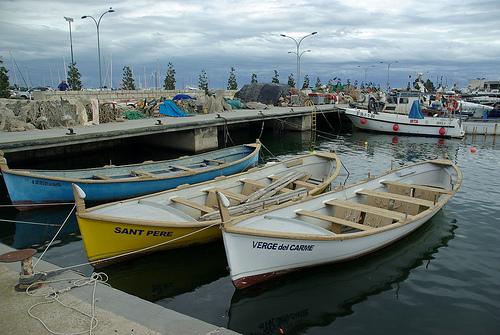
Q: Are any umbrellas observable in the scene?
A: No, there are no umbrellas.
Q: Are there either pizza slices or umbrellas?
A: No, there are no umbrellas or pizza slices.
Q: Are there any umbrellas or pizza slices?
A: No, there are no umbrellas or pizza slices.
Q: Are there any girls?
A: No, there are no girls.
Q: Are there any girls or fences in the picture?
A: No, there are no girls or fences.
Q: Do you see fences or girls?
A: No, there are no girls or fences.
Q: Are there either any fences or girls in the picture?
A: No, there are no girls or fences.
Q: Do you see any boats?
A: Yes, there is a boat.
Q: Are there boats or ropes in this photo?
A: Yes, there is a boat.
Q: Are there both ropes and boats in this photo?
A: Yes, there are both a boat and a rope.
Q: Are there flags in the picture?
A: No, there are no flags.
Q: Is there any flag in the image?
A: No, there are no flags.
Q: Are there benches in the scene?
A: Yes, there is a bench.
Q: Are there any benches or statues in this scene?
A: Yes, there is a bench.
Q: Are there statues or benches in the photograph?
A: Yes, there is a bench.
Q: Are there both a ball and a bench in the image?
A: No, there is a bench but no balls.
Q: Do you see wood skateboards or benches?
A: Yes, there is a wood bench.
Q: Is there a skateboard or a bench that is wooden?
A: Yes, the bench is wooden.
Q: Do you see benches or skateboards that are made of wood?
A: Yes, the bench is made of wood.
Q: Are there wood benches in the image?
A: Yes, there is a wood bench.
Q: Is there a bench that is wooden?
A: Yes, there is a bench that is wooden.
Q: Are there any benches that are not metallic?
A: Yes, there is a wooden bench.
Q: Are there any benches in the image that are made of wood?
A: Yes, there is a bench that is made of wood.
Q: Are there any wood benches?
A: Yes, there is a bench that is made of wood.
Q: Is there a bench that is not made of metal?
A: Yes, there is a bench that is made of wood.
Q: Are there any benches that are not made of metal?
A: Yes, there is a bench that is made of wood.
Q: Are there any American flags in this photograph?
A: No, there are no American flags.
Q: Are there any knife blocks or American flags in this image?
A: No, there are no American flags or knife blocks.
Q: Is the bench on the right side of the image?
A: Yes, the bench is on the right of the image.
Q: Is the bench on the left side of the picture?
A: No, the bench is on the right of the image.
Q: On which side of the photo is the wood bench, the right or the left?
A: The bench is on the right of the image.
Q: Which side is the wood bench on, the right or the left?
A: The bench is on the right of the image.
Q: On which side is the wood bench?
A: The bench is on the right of the image.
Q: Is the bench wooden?
A: Yes, the bench is wooden.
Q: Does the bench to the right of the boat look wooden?
A: Yes, the bench is wooden.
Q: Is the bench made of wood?
A: Yes, the bench is made of wood.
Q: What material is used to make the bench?
A: The bench is made of wood.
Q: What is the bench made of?
A: The bench is made of wood.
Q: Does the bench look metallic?
A: No, the bench is wooden.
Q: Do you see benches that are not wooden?
A: No, there is a bench but it is wooden.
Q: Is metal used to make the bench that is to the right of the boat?
A: No, the bench is made of wood.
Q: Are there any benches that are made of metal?
A: No, there is a bench but it is made of wood.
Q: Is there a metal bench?
A: No, there is a bench but it is made of wood.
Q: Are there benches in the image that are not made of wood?
A: No, there is a bench but it is made of wood.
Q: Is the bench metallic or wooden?
A: The bench is wooden.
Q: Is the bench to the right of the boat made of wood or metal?
A: The bench is made of wood.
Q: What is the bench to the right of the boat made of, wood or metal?
A: The bench is made of wood.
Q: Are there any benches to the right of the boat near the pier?
A: Yes, there is a bench to the right of the boat.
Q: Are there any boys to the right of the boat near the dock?
A: No, there is a bench to the right of the boat.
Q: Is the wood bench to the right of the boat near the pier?
A: Yes, the bench is to the right of the boat.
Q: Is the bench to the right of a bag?
A: No, the bench is to the right of the boat.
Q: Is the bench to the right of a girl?
A: No, the bench is to the right of the boat.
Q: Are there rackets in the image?
A: No, there are no rackets.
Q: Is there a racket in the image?
A: No, there are no rackets.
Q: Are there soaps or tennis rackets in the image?
A: No, there are no tennis rackets or soaps.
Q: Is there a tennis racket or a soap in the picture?
A: No, there are no rackets or soaps.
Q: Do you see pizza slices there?
A: No, there are no pizza slices.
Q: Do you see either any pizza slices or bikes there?
A: No, there are no pizza slices or bikes.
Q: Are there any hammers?
A: No, there are no hammers.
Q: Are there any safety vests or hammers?
A: No, there are no hammers or safety vests.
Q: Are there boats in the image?
A: Yes, there is a boat.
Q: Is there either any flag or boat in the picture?
A: Yes, there is a boat.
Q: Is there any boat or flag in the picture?
A: Yes, there is a boat.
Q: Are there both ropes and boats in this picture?
A: Yes, there are both a boat and a rope.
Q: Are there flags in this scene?
A: No, there are no flags.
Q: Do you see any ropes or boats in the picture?
A: Yes, there is a boat.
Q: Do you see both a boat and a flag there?
A: No, there is a boat but no flags.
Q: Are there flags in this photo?
A: No, there are no flags.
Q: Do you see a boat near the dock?
A: Yes, there is a boat near the dock.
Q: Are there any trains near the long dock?
A: No, there is a boat near the dock.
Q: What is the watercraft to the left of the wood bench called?
A: The watercraft is a boat.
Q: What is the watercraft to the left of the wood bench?
A: The watercraft is a boat.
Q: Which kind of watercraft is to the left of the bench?
A: The watercraft is a boat.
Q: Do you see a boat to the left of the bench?
A: Yes, there is a boat to the left of the bench.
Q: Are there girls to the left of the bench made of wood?
A: No, there is a boat to the left of the bench.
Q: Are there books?
A: No, there are no books.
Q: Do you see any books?
A: No, there are no books.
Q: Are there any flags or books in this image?
A: No, there are no books or flags.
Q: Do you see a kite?
A: No, there are no kites.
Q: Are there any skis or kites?
A: No, there are no kites or skis.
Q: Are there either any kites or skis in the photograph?
A: No, there are no kites or skis.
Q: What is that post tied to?
A: The post is tied to the boat.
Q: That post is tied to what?
A: The post is tied to the boat.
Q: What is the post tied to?
A: The post is tied to the boat.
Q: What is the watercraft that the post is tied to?
A: The watercraft is a boat.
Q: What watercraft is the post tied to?
A: The post is tied to the boat.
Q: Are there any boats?
A: Yes, there is a boat.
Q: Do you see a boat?
A: Yes, there is a boat.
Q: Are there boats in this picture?
A: Yes, there is a boat.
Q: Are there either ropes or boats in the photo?
A: Yes, there is a boat.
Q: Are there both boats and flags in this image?
A: No, there is a boat but no flags.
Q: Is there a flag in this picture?
A: No, there are no flags.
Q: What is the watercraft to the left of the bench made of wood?
A: The watercraft is a boat.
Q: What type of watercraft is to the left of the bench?
A: The watercraft is a boat.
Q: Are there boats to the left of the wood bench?
A: Yes, there is a boat to the left of the bench.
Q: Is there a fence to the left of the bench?
A: No, there is a boat to the left of the bench.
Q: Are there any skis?
A: No, there are no skis.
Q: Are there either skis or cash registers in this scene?
A: No, there are no skis or cash registers.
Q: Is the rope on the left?
A: Yes, the rope is on the left of the image.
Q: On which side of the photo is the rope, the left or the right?
A: The rope is on the left of the image.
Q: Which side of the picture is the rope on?
A: The rope is on the left of the image.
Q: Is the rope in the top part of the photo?
A: No, the rope is in the bottom of the image.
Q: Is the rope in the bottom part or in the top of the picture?
A: The rope is in the bottom of the image.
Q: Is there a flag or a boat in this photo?
A: Yes, there is a boat.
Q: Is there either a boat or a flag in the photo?
A: Yes, there is a boat.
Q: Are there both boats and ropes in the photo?
A: Yes, there are both a boat and a rope.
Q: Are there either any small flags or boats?
A: Yes, there is a small boat.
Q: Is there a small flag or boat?
A: Yes, there is a small boat.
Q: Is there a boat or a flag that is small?
A: Yes, the boat is small.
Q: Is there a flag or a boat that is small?
A: Yes, the boat is small.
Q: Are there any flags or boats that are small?
A: Yes, the boat is small.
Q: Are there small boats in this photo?
A: Yes, there is a small boat.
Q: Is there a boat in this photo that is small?
A: Yes, there is a boat that is small.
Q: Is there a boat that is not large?
A: Yes, there is a small boat.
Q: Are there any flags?
A: No, there are no flags.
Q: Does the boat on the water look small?
A: Yes, the boat is small.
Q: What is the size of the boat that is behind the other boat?
A: The boat is small.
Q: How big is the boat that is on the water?
A: The boat is small.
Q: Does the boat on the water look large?
A: No, the boat is small.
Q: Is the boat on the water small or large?
A: The boat is small.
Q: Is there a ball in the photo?
A: No, there are no balls.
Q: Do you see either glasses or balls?
A: No, there are no balls or glasses.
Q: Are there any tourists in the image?
A: No, there are no tourists.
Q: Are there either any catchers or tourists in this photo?
A: No, there are no tourists or catchers.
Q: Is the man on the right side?
A: Yes, the man is on the right of the image.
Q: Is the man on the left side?
A: No, the man is on the right of the image.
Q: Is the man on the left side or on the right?
A: The man is on the right of the image.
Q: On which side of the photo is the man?
A: The man is on the right of the image.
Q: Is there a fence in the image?
A: No, there are no fences.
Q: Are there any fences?
A: No, there are no fences.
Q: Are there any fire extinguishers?
A: No, there are no fire extinguishers.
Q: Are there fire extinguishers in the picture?
A: No, there are no fire extinguishers.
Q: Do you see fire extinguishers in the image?
A: No, there are no fire extinguishers.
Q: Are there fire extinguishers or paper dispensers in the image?
A: No, there are no fire extinguishers or paper dispensers.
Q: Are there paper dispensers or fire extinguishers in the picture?
A: No, there are no fire extinguishers or paper dispensers.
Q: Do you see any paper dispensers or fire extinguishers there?
A: No, there are no fire extinguishers or paper dispensers.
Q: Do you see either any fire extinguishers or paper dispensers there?
A: No, there are no fire extinguishers or paper dispensers.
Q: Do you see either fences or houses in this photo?
A: No, there are no fences or houses.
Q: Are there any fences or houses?
A: No, there are no fences or houses.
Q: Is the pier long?
A: Yes, the pier is long.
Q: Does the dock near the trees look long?
A: Yes, the dock is long.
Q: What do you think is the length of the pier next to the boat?
A: The dock is long.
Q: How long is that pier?
A: The pier is long.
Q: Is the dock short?
A: No, the dock is long.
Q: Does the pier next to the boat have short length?
A: No, the pier is long.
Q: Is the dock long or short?
A: The dock is long.